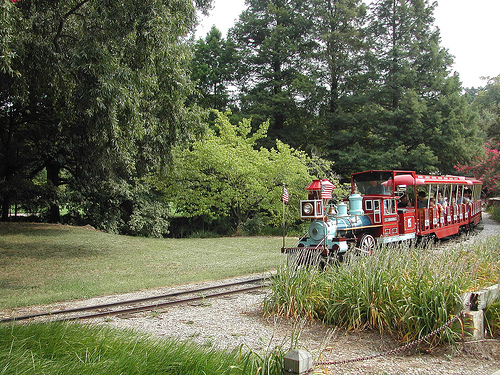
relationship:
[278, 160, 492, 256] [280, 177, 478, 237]
train on track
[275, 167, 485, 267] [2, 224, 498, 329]
train on track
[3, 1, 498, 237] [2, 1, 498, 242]
leaves on trees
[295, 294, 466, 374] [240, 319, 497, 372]
chain over path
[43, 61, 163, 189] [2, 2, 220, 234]
branches on tree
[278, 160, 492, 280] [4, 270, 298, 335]
train on tracks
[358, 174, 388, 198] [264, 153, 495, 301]
conductor driving train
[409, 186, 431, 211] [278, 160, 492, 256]
pasengers riding in train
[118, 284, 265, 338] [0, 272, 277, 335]
gravel around tracks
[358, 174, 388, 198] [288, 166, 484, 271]
conductor driving train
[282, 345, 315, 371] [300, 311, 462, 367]
post that holds of chain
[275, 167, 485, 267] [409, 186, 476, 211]
train with pasengers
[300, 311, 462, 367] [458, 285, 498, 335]
chain connected post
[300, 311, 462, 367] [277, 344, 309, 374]
chain connected post